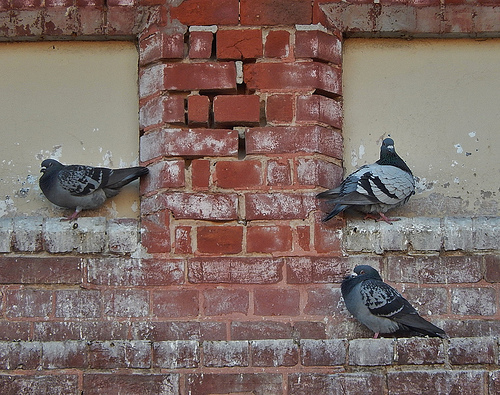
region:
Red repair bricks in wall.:
[177, 31, 289, 149]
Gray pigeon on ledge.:
[323, 253, 449, 334]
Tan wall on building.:
[347, 42, 499, 215]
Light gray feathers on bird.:
[334, 158, 421, 222]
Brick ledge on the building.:
[2, 215, 154, 262]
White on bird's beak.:
[376, 135, 397, 159]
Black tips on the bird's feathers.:
[335, 154, 414, 216]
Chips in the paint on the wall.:
[438, 123, 492, 173]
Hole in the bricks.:
[227, 54, 252, 102]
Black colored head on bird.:
[337, 258, 389, 300]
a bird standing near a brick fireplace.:
[313, 132, 424, 237]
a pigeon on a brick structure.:
[327, 254, 448, 337]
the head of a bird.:
[19, 150, 66, 197]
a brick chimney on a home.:
[128, 13, 355, 218]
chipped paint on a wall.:
[464, 120, 481, 147]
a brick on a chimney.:
[257, 22, 295, 58]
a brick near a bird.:
[152, 283, 202, 323]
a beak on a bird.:
[343, 265, 361, 282]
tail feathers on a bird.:
[312, 173, 362, 224]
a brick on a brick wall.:
[295, 335, 354, 374]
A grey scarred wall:
[437, 160, 496, 212]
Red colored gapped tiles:
[161, 31, 290, 169]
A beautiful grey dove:
[35, 155, 148, 227]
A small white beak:
[352, 268, 357, 278]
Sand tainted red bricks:
[397, 217, 489, 254]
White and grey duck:
[311, 135, 431, 227]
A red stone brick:
[204, 91, 266, 126]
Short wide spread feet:
[353, 210, 401, 225]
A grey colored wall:
[21, 81, 116, 118]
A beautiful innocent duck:
[325, 256, 455, 356]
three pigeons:
[30, 135, 492, 358]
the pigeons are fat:
[6, 114, 483, 394]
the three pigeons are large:
[26, 91, 493, 393]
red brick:
[152, 13, 343, 385]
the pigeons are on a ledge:
[19, 119, 480, 384]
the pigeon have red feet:
[53, 209, 419, 261]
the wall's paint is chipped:
[415, 98, 499, 211]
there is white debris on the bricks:
[143, 55, 336, 382]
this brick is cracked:
[214, 29, 264, 62]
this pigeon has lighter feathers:
[313, 122, 463, 257]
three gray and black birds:
[38, 100, 445, 330]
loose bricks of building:
[172, 23, 275, 180]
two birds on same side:
[330, 119, 455, 339]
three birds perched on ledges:
[5, 133, 495, 348]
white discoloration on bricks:
[14, 203, 489, 390]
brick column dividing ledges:
[140, 26, 335, 244]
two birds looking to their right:
[39, 154, 441, 345]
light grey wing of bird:
[352, 162, 414, 201]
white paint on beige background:
[12, 128, 488, 205]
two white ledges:
[8, 210, 498, 257]